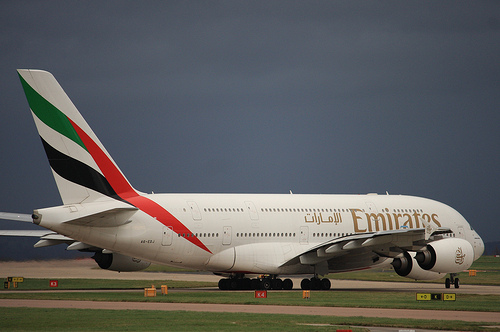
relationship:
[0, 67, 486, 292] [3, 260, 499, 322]
plane on top of runway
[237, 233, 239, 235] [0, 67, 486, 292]
window on side of plane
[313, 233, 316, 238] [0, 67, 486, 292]
window on side of plane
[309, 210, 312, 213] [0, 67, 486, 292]
window on side of plane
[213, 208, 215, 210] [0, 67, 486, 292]
window on side of plane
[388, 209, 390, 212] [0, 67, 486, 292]
window on side of plane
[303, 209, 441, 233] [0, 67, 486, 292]
words on side of plane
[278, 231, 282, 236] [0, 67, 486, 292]
window on side of plane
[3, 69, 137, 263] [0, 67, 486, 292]
tail of plane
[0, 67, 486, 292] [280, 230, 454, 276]
plane has wing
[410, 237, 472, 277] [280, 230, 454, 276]
engine hanging on wing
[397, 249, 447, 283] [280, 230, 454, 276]
engine hanging on wing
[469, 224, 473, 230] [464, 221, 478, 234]
window of cockpit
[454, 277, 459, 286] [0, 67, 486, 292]
wheel on front of plane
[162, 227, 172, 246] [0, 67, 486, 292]
door on side of plane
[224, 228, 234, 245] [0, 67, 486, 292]
door on side of plane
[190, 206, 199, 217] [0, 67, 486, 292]
door on side of plane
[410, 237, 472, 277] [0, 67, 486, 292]
engine on side of plane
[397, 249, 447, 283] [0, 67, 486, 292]
engine on side of plane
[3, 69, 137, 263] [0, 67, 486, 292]
tail on back of plane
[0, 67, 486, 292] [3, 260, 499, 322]
plane parked on runway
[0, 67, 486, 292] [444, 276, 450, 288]
plane with wheel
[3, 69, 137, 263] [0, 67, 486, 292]
tail on end of plane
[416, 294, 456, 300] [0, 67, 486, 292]
sign near plane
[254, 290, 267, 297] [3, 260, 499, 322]
sign on runway